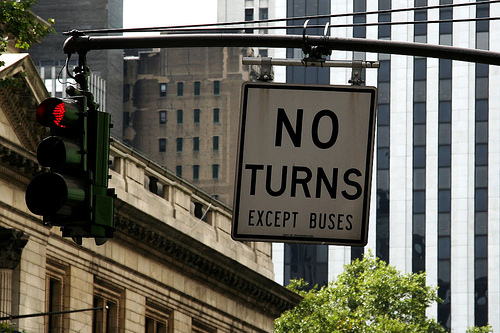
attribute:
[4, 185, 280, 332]
wall — old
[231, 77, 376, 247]
sign — large, square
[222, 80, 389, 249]
street sign — rusty, hanging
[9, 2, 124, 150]
building — tall, gray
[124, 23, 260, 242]
building — brown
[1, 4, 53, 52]
tree — tall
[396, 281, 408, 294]
leaf — bright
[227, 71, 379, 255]
board — edge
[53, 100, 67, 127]
light — on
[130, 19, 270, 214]
building — brown, old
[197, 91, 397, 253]
border — black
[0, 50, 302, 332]
building — tall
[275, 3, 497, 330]
building — tall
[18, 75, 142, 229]
light — red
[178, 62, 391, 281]
board — edge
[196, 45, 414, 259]
sign — white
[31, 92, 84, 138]
light — red